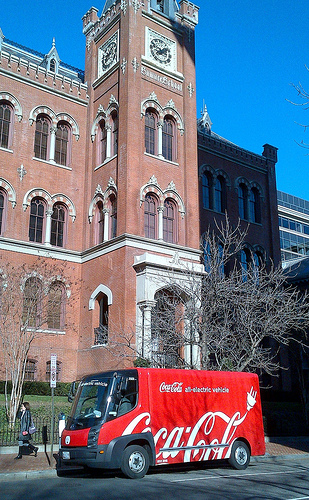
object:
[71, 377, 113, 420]
front window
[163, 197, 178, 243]
windows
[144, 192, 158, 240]
window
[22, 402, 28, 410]
head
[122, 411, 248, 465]
lettering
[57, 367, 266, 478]
bus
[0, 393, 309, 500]
ground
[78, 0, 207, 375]
tower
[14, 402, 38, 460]
person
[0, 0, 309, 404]
buildings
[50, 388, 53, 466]
pole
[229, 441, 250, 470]
truckwheel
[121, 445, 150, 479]
truckwheel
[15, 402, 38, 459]
walker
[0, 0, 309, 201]
sky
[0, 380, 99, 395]
hedge bushes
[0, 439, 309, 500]
road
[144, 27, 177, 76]
clock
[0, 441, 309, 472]
sidewalk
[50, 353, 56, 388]
sign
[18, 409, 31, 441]
jacket